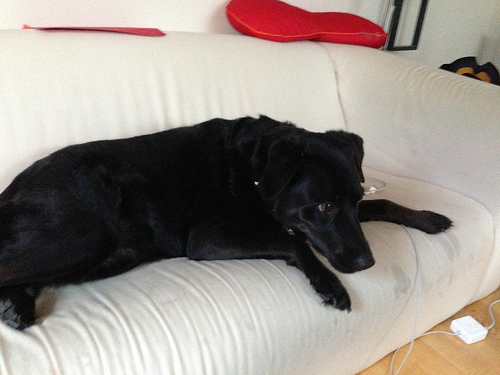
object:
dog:
[3, 112, 458, 331]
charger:
[365, 175, 498, 375]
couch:
[2, 23, 500, 372]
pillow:
[225, 2, 393, 47]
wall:
[5, 1, 500, 90]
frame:
[386, 0, 431, 55]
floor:
[426, 345, 500, 373]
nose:
[357, 255, 374, 271]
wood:
[436, 351, 500, 375]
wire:
[366, 173, 448, 367]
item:
[23, 23, 168, 37]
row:
[42, 60, 257, 147]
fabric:
[0, 35, 499, 375]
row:
[0, 47, 457, 349]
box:
[449, 313, 487, 348]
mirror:
[383, 1, 437, 57]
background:
[3, 2, 499, 141]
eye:
[316, 200, 333, 214]